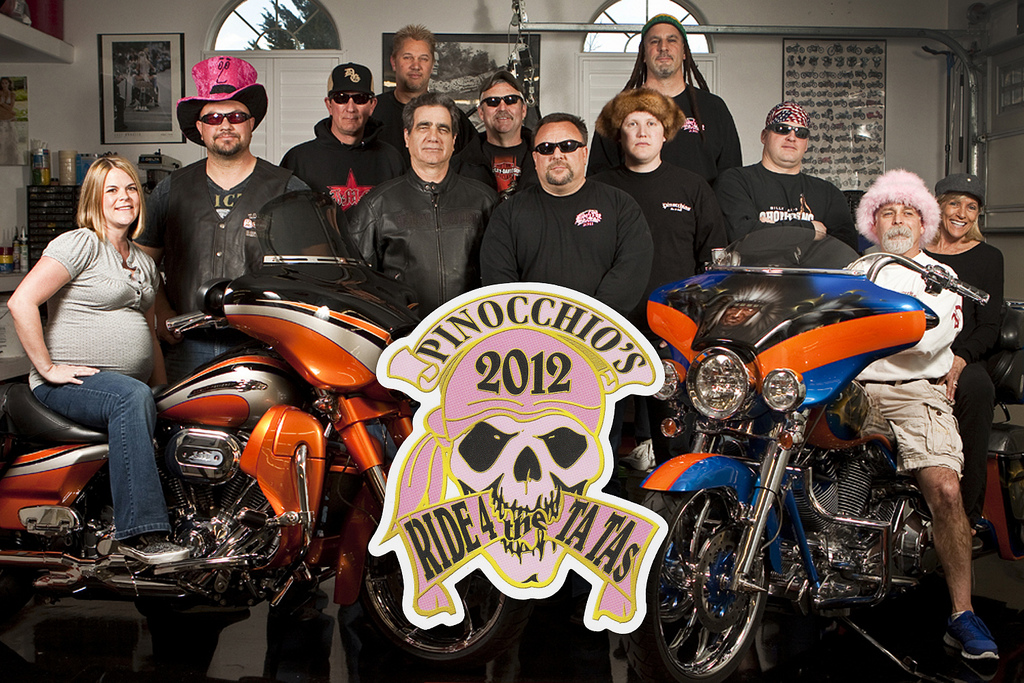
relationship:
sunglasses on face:
[525, 131, 584, 161] [521, 113, 589, 185]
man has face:
[480, 112, 654, 321] [521, 113, 589, 185]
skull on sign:
[354, 276, 672, 653] [376, 279, 667, 634]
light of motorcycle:
[683, 346, 760, 430] [620, 255, 957, 679]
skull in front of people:
[366, 281, 668, 636] [5, 7, 1010, 669]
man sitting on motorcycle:
[824, 169, 1008, 660] [620, 255, 957, 679]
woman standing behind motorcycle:
[929, 172, 1002, 483] [603, 249, 986, 675]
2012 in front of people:
[473, 341, 578, 399] [5, 7, 1010, 669]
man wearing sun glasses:
[480, 113, 629, 298] [534, 134, 601, 161]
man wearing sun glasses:
[736, 93, 858, 249] [768, 122, 816, 149]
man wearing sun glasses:
[135, 49, 317, 306] [193, 102, 256, 135]